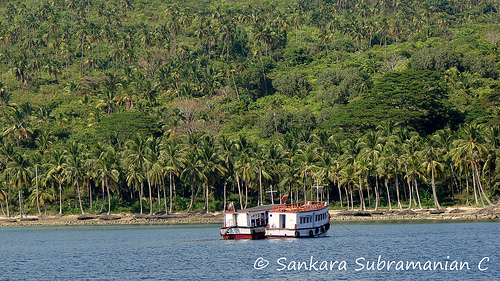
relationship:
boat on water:
[264, 200, 330, 239] [3, 224, 498, 277]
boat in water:
[222, 203, 258, 239] [3, 224, 498, 277]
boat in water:
[269, 208, 329, 239] [3, 224, 498, 277]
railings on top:
[276, 207, 327, 212] [274, 200, 325, 211]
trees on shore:
[3, 167, 499, 213] [5, 209, 500, 224]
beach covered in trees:
[8, 218, 498, 225] [3, 167, 499, 213]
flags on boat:
[225, 202, 236, 216] [222, 203, 258, 239]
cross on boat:
[264, 185, 285, 208] [222, 203, 258, 239]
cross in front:
[264, 185, 285, 208] [255, 198, 280, 210]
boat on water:
[222, 203, 258, 239] [3, 224, 498, 277]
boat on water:
[269, 208, 329, 239] [3, 224, 498, 277]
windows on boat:
[302, 215, 332, 222] [264, 200, 330, 239]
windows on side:
[302, 215, 332, 222] [299, 212, 336, 238]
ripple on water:
[34, 244, 143, 274] [3, 224, 498, 277]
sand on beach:
[5, 209, 500, 224] [0, 119, 495, 217]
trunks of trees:
[5, 192, 492, 216] [3, 167, 499, 213]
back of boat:
[267, 209, 301, 237] [269, 208, 329, 239]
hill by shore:
[8, 9, 499, 178] [5, 209, 500, 224]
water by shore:
[3, 224, 498, 277] [5, 209, 500, 224]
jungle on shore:
[8, 9, 499, 178] [2, 189, 496, 224]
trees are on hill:
[8, 9, 499, 178] [0, 5, 490, 205]